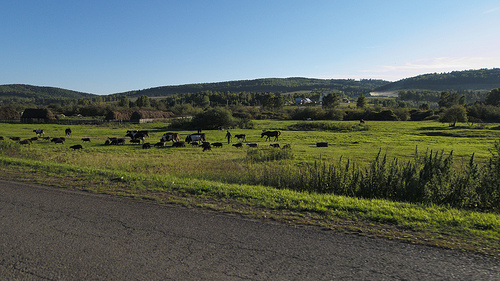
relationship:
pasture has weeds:
[10, 117, 494, 178] [262, 158, 490, 200]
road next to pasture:
[12, 178, 291, 276] [10, 117, 494, 178]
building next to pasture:
[14, 110, 56, 121] [10, 117, 494, 178]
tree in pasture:
[194, 108, 242, 133] [10, 117, 494, 178]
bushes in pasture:
[303, 108, 345, 122] [10, 117, 494, 178]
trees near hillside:
[331, 101, 478, 122] [399, 64, 496, 113]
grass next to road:
[69, 187, 497, 230] [12, 178, 291, 276]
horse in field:
[258, 127, 282, 140] [10, 117, 494, 178]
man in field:
[224, 127, 235, 143] [15, 124, 496, 221]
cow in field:
[186, 133, 207, 145] [15, 124, 496, 221]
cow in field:
[160, 133, 182, 144] [15, 124, 496, 221]